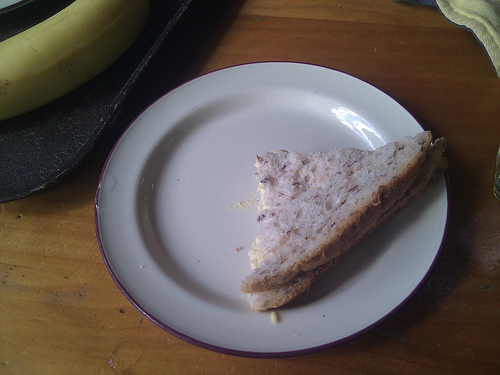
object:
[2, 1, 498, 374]
table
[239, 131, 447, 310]
sandwich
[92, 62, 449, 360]
plate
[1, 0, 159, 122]
banana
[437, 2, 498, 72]
fabric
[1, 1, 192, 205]
tray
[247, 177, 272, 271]
eggs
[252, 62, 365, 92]
rim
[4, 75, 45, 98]
spots